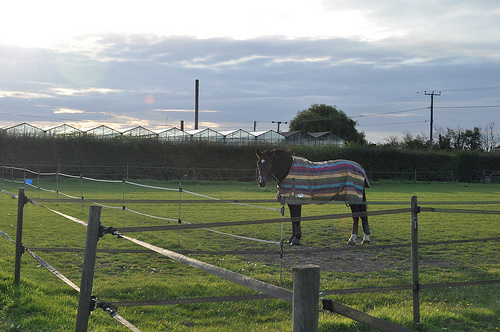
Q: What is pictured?
A: A horse.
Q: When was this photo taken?
A: Early morning.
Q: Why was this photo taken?
A: To show the horse.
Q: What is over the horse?
A: A horse blanket.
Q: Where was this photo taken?
A: In a field.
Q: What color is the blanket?
A: It is striped, grey, pink, blue, and yellow.